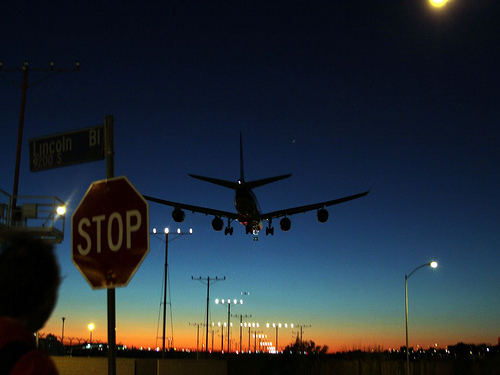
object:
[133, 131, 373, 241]
plane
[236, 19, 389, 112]
night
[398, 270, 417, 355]
light pole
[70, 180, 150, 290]
stop sign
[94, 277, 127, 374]
pole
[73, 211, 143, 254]
lettering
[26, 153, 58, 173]
numbers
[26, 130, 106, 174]
street sign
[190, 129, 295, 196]
tail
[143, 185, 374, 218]
wings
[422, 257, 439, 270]
street light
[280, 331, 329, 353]
trees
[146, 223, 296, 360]
street lights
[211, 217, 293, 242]
wheels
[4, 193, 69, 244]
platform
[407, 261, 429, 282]
arm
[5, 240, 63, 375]
person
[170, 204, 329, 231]
engines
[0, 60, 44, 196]
pole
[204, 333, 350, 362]
runway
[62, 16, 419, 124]
sky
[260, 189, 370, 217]
wing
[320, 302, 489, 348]
sky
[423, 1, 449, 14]
moon